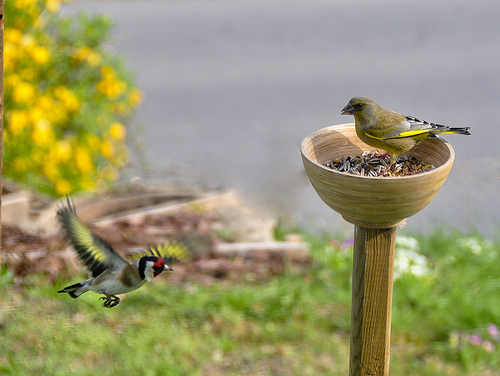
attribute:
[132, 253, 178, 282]
head — black 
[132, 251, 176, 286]
face — white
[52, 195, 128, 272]
wingfeathers — interspersed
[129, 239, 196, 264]
wingfeathers — interspersed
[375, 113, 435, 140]
wingfeathers — interspersed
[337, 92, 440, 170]
goldfinch — male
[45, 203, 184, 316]
goldfinch — female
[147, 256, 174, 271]
face — red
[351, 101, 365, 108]
eye — black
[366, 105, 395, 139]
feathers — red